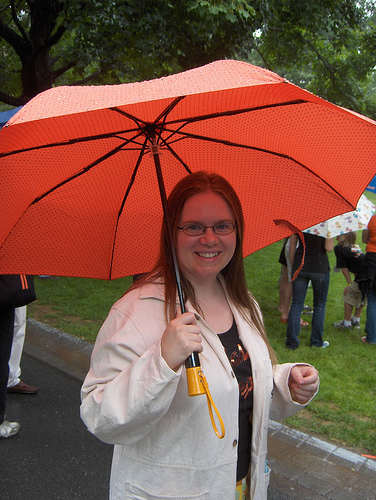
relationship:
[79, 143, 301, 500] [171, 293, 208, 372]
woman has hands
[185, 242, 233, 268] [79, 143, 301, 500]
smile on woman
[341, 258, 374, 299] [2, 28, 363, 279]
boy under umbrella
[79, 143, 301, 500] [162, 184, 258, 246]
woman wearing glass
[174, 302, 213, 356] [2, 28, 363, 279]
hand holding umbrella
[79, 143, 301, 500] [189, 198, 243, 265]
woman has face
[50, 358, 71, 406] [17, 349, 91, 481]
edge of road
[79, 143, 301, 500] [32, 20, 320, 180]
woman in rain